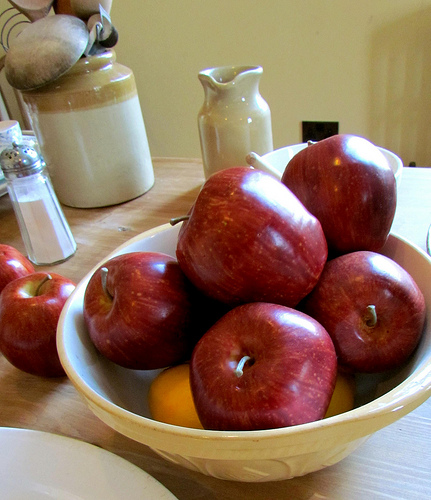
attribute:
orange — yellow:
[153, 359, 204, 432]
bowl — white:
[50, 209, 428, 484]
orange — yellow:
[320, 369, 354, 419]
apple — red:
[279, 133, 399, 259]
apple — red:
[168, 165, 325, 311]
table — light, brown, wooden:
[2, 155, 429, 500]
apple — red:
[82, 252, 200, 370]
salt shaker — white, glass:
[0, 145, 77, 266]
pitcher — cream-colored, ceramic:
[196, 65, 275, 180]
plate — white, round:
[1, 428, 185, 500]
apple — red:
[190, 302, 336, 431]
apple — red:
[307, 251, 427, 372]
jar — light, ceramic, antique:
[12, 47, 156, 209]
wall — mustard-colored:
[0, 0, 430, 168]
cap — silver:
[1, 146, 44, 180]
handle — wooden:
[247, 151, 281, 180]